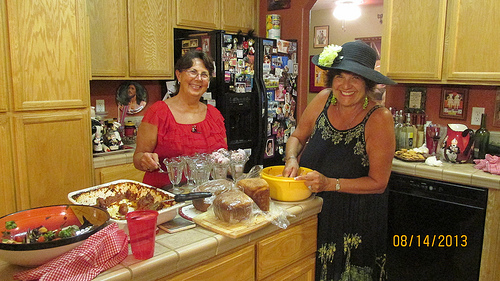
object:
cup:
[126, 211, 159, 259]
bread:
[212, 190, 252, 224]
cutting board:
[192, 209, 279, 239]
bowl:
[258, 165, 316, 202]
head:
[326, 67, 377, 106]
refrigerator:
[171, 21, 303, 176]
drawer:
[255, 217, 318, 280]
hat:
[312, 31, 395, 83]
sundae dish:
[165, 155, 184, 202]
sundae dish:
[184, 152, 199, 185]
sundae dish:
[188, 153, 209, 188]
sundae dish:
[213, 154, 230, 182]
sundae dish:
[226, 149, 248, 180]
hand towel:
[10, 224, 132, 281]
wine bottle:
[474, 114, 492, 159]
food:
[283, 163, 299, 178]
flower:
[317, 43, 343, 67]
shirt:
[141, 100, 228, 190]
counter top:
[392, 145, 499, 178]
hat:
[312, 42, 398, 84]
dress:
[295, 88, 404, 281]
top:
[165, 147, 242, 169]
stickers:
[197, 38, 314, 153]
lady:
[132, 51, 226, 189]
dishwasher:
[381, 173, 485, 281]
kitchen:
[0, 0, 500, 281]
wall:
[90, 0, 307, 178]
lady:
[283, 40, 398, 281]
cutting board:
[179, 202, 214, 221]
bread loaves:
[213, 179, 270, 224]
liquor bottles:
[393, 109, 426, 148]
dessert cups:
[162, 149, 251, 195]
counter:
[0, 184, 324, 280]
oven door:
[379, 198, 481, 280]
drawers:
[170, 218, 317, 281]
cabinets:
[173, 0, 257, 32]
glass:
[129, 211, 155, 260]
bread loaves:
[194, 178, 271, 224]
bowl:
[1, 204, 110, 266]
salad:
[1, 214, 91, 243]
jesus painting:
[115, 82, 148, 114]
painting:
[438, 89, 468, 120]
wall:
[304, 0, 498, 155]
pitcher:
[441, 124, 476, 164]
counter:
[392, 156, 499, 188]